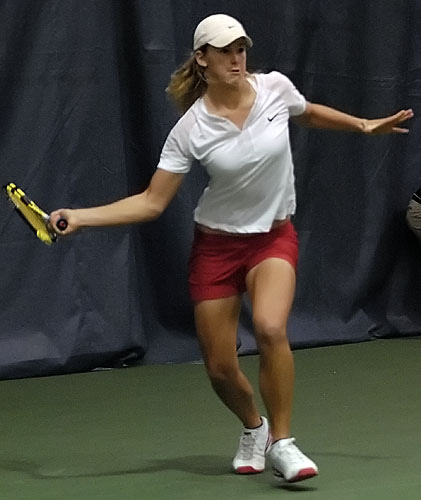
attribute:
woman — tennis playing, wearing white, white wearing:
[49, 14, 411, 479]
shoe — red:
[262, 434, 321, 487]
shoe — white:
[264, 436, 322, 489]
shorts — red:
[177, 219, 294, 276]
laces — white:
[241, 435, 257, 455]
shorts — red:
[190, 237, 266, 298]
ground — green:
[47, 405, 143, 473]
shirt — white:
[203, 127, 288, 228]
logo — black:
[265, 110, 284, 124]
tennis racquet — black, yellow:
[2, 179, 67, 244]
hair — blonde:
[177, 64, 203, 98]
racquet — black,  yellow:
[5, 181, 67, 246]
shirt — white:
[182, 98, 292, 232]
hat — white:
[199, 16, 247, 45]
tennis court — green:
[65, 386, 197, 470]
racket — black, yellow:
[5, 179, 68, 248]